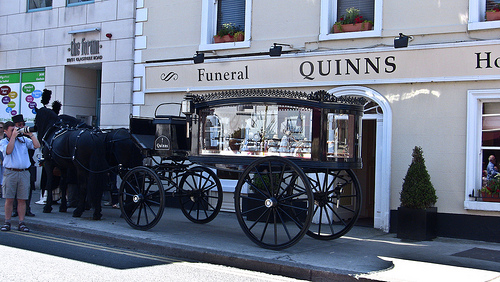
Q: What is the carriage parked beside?
A: A funeral home.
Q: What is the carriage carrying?
A: A glass coffin.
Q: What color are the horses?
A: Black.